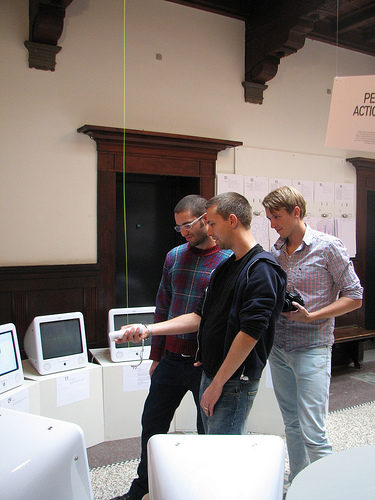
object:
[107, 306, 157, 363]
tv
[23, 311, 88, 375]
tv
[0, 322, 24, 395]
tv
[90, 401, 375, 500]
rug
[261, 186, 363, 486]
man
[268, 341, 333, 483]
jeans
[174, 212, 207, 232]
glasses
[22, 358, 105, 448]
box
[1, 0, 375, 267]
wall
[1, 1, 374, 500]
room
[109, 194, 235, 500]
man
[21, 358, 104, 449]
table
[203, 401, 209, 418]
finger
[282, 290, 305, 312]
camera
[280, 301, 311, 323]
hand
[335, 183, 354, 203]
papers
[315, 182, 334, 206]
papers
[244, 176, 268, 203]
papers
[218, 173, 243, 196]
papers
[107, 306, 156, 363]
computer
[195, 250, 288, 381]
hoodie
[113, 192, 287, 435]
man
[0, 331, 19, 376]
monitor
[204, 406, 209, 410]
ring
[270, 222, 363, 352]
man shirt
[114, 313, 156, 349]
monitor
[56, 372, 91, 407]
paper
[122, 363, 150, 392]
paper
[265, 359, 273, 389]
paper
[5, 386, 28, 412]
paper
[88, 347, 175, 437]
box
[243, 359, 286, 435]
box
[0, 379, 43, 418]
box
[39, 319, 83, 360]
monitor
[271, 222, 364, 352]
button-up shirt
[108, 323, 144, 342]
game controller